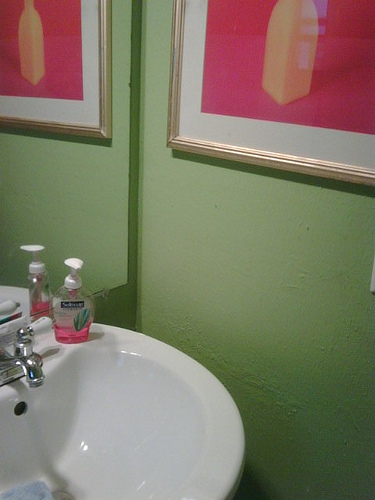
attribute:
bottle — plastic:
[48, 257, 96, 344]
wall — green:
[144, 5, 372, 499]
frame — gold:
[165, 0, 373, 189]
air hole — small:
[12, 399, 30, 416]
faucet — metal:
[11, 321, 67, 388]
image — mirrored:
[0, 0, 115, 146]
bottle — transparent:
[58, 257, 94, 347]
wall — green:
[92, 9, 371, 432]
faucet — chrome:
[12, 326, 45, 382]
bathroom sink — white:
[0, 314, 249, 498]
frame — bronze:
[157, 31, 205, 203]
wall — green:
[177, 201, 312, 338]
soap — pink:
[53, 312, 95, 337]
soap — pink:
[52, 323, 90, 342]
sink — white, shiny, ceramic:
[6, 317, 248, 498]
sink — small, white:
[0, 329, 234, 488]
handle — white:
[16, 320, 36, 343]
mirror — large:
[1, 0, 133, 327]